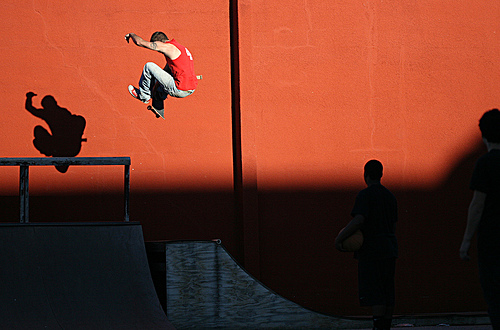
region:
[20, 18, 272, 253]
the man is doing tricks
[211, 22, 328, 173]
the wall is red orange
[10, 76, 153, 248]
the shadow is on the wall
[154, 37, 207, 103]
the shirt is red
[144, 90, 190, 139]
the skateboard is black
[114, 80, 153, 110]
the sneaker is red and white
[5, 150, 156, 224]
the bars are faded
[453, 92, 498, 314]
the boy is standing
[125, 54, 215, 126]
man is wearing jeans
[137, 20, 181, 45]
the hair is brown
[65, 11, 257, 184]
a skateboarder in the air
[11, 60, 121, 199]
a skateboarder's shadow on the wall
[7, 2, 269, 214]
a skateboarder and his shadow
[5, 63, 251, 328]
skateboard ramps at the skatepark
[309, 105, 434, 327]
a boy holding a ball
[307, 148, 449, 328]
a boy watching the skateboarder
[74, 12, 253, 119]
a skateboarder doing a trick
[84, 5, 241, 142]
a skateboarder doing a stunt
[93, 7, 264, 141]
a skateboarder high above the ramp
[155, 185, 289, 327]
a wooden skate ramp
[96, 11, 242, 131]
the man is skateboarding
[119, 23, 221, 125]
the man is in the air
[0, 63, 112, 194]
the shadow of the skateboarder is on the wall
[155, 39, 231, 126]
the man's shirt is red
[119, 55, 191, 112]
the man is wearing blue jeans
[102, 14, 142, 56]
the man is wearing a watch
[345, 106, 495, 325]
2 people are watching the skateboarder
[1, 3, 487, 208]
the wall is orange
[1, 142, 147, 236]
the ramp is made of metal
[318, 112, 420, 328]
the man is holding a skateboard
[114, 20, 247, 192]
a skateboarder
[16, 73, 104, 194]
a skateboarder's shadow on wall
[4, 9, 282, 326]
a skateboarder at skatepark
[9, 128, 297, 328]
skateboard ramps in a park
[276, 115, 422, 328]
a man standing with a ball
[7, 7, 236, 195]
a skateboard and his shadow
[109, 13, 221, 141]
a skateboard doing a stunt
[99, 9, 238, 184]
a skateboard wearing a red shirt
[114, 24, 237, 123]
a skateboard wearing jeans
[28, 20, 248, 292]
the skateboarder is catching air off a halfpipe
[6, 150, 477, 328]
two hail pipes are in the park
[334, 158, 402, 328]
the boy is holding a ball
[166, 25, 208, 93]
the boy is wearing a red shirt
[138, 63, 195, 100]
the boy has khaki pants on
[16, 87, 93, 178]
the shadow of the skateboarder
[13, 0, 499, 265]
the wall is painted red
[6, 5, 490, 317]
the sun is shining on half the wall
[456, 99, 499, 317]
a spectator is wearing a t-shirt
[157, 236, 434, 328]
the half pipe is wooden